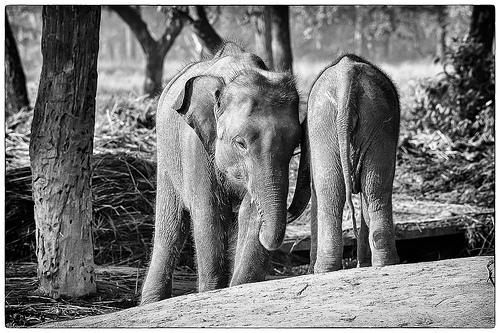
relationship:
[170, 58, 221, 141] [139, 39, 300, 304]
ear of baby elephant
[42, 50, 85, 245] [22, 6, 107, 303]
bark on trunk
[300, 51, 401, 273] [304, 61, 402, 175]
baby elephants showing h but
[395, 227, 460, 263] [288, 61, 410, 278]
dark cave next to elephants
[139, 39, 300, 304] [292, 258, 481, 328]
baby elephant on ground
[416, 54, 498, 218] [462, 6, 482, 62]
foliage under tree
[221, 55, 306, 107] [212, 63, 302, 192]
baby hair on an elephant head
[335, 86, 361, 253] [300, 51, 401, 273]
elephant tail hanging down baby elephants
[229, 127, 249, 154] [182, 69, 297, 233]
eye on side of head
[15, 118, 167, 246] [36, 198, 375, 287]
straw on ground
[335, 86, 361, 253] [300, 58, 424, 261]
elephant tail of elephant